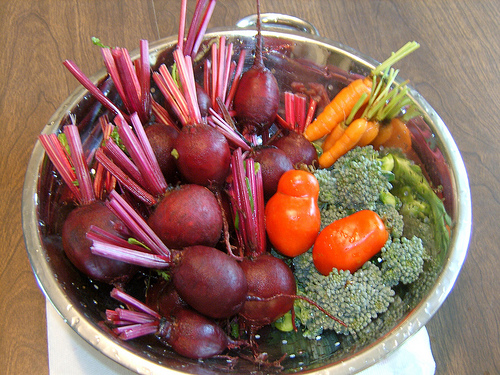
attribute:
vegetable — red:
[75, 96, 207, 240]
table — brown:
[0, 0, 499, 374]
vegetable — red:
[230, 150, 297, 322]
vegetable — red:
[108, 289, 253, 356]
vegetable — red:
[40, 130, 129, 278]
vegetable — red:
[153, 50, 232, 185]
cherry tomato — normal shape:
[269, 170, 322, 256]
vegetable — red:
[41, 32, 323, 367]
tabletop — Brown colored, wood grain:
[0, 1, 498, 374]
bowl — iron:
[12, 17, 484, 372]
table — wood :
[9, 20, 67, 62]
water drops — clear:
[339, 231, 356, 243]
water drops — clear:
[290, 213, 302, 223]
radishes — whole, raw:
[238, 2, 281, 137]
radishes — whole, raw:
[269, 90, 319, 167]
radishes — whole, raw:
[207, 96, 295, 192]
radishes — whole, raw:
[167, 2, 214, 126]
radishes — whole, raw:
[154, 50, 230, 184]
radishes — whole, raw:
[61, 36, 183, 182]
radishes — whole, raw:
[95, 112, 225, 246]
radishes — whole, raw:
[229, 148, 296, 327]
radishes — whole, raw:
[84, 187, 246, 317]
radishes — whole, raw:
[39, 124, 139, 284]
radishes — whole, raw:
[103, 286, 259, 359]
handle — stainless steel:
[236, 12, 320, 45]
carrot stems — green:
[361, 62, 428, 113]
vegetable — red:
[232, 0, 279, 136]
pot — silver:
[21, 9, 471, 374]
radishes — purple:
[85, 67, 284, 351]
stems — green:
[344, 41, 431, 123]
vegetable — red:
[144, 179, 230, 244]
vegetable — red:
[88, 191, 250, 322]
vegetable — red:
[142, 51, 238, 196]